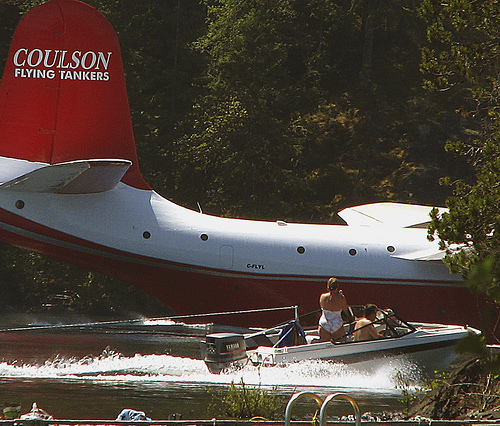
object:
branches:
[432, 142, 500, 311]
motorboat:
[203, 320, 483, 377]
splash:
[5, 340, 425, 412]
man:
[352, 304, 378, 342]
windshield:
[333, 300, 418, 340]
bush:
[200, 372, 295, 419]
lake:
[2, 355, 197, 392]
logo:
[13, 42, 111, 82]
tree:
[177, 16, 386, 198]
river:
[0, 301, 499, 423]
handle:
[318, 392, 362, 425]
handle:
[281, 391, 325, 425]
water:
[32, 345, 203, 386]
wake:
[45, 342, 207, 391]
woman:
[312, 275, 347, 343]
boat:
[202, 303, 483, 375]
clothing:
[116, 407, 153, 421]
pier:
[6, 415, 341, 424]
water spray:
[277, 358, 422, 389]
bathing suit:
[318, 307, 343, 334]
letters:
[246, 263, 265, 269]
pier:
[7, 394, 499, 424]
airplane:
[0, 0, 500, 345]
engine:
[199, 333, 248, 375]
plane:
[0, 0, 500, 338]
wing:
[333, 201, 452, 228]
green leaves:
[433, 186, 500, 281]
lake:
[12, 385, 229, 409]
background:
[9, 0, 500, 166]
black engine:
[204, 330, 248, 374]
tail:
[1, 0, 155, 190]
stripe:
[310, 320, 482, 382]